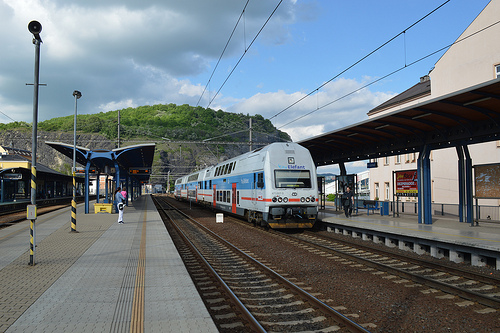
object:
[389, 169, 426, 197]
sign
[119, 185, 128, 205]
person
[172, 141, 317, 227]
train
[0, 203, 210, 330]
platform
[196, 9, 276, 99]
wire line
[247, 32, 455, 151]
wire line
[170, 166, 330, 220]
train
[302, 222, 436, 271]
tracks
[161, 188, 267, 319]
tracks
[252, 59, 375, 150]
clouds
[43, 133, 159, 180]
roofs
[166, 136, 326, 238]
train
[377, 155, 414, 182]
ground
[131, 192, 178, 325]
platform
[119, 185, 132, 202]
books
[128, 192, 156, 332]
line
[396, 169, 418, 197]
advertisement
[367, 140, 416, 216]
wall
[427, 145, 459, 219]
wall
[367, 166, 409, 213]
window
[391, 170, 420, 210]
sign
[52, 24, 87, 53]
clouds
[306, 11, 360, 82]
sky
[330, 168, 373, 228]
person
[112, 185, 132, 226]
mother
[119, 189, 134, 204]
baby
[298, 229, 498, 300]
train track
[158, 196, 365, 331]
train track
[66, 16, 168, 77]
white clouds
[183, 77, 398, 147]
white clouds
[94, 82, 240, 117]
white clouds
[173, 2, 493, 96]
blue sky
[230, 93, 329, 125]
cloud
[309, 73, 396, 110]
cloud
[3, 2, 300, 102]
cloud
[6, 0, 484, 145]
sky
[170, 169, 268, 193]
stripe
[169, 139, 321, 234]
train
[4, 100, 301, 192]
mountain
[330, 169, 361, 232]
man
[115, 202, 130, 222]
pants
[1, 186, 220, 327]
platform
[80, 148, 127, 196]
supports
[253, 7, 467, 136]
sky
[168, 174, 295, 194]
stripes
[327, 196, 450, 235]
platform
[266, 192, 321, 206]
headlights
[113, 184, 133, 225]
woman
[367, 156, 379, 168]
chain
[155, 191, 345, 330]
tracks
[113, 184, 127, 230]
person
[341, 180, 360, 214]
person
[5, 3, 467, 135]
sky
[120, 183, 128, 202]
baby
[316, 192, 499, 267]
platform